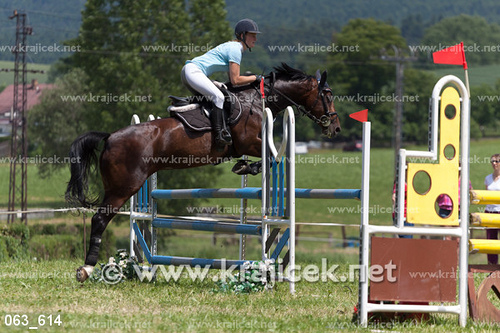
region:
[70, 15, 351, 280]
equestrian jumping a fence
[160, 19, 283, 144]
English style rider on a horse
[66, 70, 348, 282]
dark brown horse jumping a fence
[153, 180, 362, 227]
post of a gate for jumping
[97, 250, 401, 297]
copywright watermark on a photo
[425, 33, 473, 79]
orange flag on a gate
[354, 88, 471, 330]
end of a gate for horse jumping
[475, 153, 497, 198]
spectator watching an equestrian event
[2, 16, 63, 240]
power line in the background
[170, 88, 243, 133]
English saddle on a horse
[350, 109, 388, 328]
This is a pole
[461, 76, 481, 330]
This is a pole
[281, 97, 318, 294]
This is a pole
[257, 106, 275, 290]
This is a pole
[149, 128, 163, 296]
This is a pole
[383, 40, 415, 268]
This is a pole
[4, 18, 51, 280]
This is a pole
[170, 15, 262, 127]
This is a person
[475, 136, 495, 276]
This is a person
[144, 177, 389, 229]
This is a rail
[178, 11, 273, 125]
this is a horse racer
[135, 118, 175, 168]
this is the horse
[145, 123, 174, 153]
the horse is brown in color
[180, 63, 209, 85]
the butt is behind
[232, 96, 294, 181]
the horse is on air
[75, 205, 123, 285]
the legs are behind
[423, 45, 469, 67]
this is a red flag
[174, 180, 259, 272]
this is a post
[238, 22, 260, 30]
she is wearing a helmet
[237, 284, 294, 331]
the grass are green in color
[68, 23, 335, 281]
horse and rider taking jump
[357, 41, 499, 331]
horse jump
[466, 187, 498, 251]
three yellow jump poles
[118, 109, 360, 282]
white and blue jump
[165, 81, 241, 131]
English jumping saddle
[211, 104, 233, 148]
black English riding boot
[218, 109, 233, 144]
stirrup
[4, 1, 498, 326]
female rider taking her horse through a jumping course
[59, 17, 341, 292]
female rider skillfully taking her horse over a jump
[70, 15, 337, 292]
brown horse takes jump with room to spare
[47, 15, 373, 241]
the horse is jumping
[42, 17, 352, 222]
he horse is brown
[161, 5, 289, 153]
the woman is riding the horse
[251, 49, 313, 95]
the mane is black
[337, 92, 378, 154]
red flag on a pole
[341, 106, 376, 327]
the pole is white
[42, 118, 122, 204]
the tail is long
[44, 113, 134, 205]
the tail is black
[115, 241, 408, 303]
letters at the bottom of the screen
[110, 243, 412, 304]
the letters are white